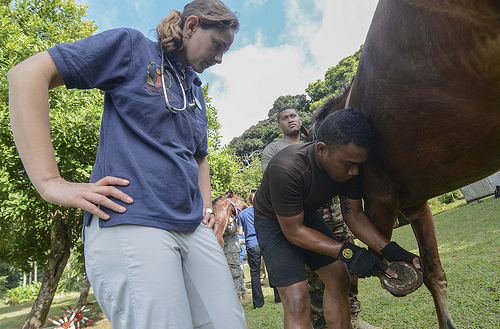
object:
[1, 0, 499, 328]
scene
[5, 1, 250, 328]
woman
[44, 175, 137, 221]
hands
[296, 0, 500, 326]
horse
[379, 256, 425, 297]
horse hoof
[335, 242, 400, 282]
hands of man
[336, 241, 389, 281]
gloves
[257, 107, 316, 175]
2nd man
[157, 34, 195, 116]
stethoscope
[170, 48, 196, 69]
neck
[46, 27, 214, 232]
t-shirt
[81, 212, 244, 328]
pants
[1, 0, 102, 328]
tree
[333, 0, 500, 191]
side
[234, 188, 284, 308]
2nd woman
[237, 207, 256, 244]
back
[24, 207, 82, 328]
trunk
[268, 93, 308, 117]
tops of trees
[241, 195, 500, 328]
grass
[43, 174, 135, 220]
woman's hand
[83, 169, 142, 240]
hip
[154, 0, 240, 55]
hair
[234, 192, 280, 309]
trainer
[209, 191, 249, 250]
horse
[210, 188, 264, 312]
horse and trainer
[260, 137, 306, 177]
grey t-shirt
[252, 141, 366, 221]
shirt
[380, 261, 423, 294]
horse shoe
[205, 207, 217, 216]
watch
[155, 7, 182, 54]
ponytail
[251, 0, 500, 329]
man and horse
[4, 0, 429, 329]
doctor and man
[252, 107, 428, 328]
people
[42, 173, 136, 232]
hands on hips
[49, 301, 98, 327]
spiky objects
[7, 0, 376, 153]
sky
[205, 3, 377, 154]
clouds